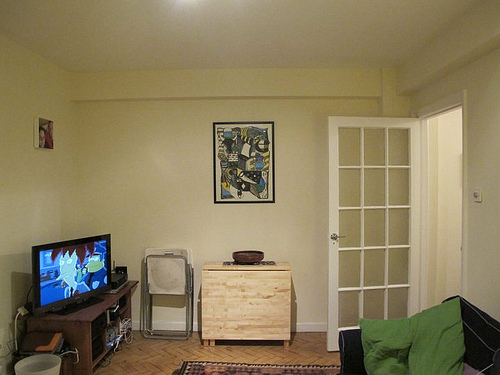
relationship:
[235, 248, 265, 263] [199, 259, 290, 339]
bowl on table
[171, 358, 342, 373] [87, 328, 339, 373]
rug on floor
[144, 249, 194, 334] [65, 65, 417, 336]
folded chairs against wall